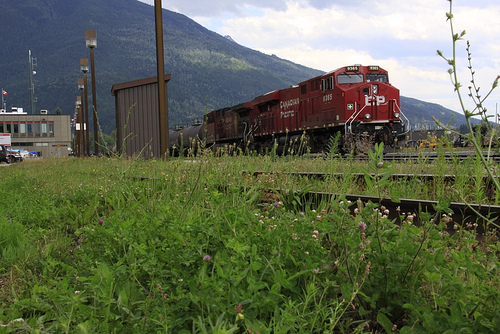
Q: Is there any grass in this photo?
A: Yes, there is grass.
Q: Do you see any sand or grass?
A: Yes, there is grass.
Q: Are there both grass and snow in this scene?
A: No, there is grass but no snow.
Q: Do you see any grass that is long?
A: Yes, there is long grass.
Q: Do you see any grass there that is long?
A: Yes, there is grass that is long.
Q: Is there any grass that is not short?
A: Yes, there is long grass.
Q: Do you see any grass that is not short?
A: Yes, there is long grass.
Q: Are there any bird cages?
A: No, there are no bird cages.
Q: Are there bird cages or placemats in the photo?
A: No, there are no bird cages or placemats.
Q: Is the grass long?
A: Yes, the grass is long.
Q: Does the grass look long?
A: Yes, the grass is long.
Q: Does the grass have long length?
A: Yes, the grass is long.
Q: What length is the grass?
A: The grass is long.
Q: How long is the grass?
A: The grass is long.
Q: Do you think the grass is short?
A: No, the grass is long.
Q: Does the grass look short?
A: No, the grass is long.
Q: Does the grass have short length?
A: No, the grass is long.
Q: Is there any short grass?
A: No, there is grass but it is long.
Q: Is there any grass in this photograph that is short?
A: No, there is grass but it is long.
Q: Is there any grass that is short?
A: No, there is grass but it is long.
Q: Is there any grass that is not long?
A: No, there is grass but it is long.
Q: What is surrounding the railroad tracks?
A: The grass is surrounding the railroad tracks.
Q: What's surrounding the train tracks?
A: The grass is surrounding the railroad tracks.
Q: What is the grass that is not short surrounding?
A: The grass is surrounding the train tracks.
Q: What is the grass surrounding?
A: The grass is surrounding the train tracks.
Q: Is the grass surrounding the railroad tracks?
A: Yes, the grass is surrounding the railroad tracks.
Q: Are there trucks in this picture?
A: Yes, there is a truck.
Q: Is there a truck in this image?
A: Yes, there is a truck.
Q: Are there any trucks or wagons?
A: Yes, there is a truck.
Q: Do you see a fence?
A: No, there are no fences.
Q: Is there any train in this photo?
A: Yes, there is a train.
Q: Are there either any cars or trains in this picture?
A: Yes, there is a train.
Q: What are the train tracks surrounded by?
A: The train tracks are surrounded by the grass.